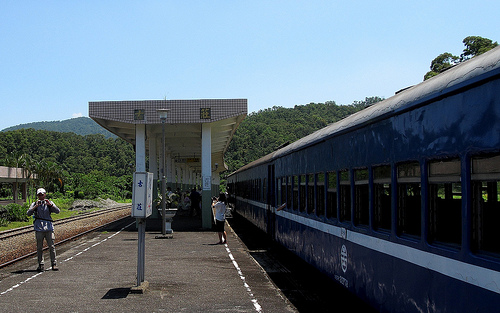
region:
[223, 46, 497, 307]
a blue train at a station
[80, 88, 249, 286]
a covering over a platform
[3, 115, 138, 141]
a mountain in the distance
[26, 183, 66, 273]
a man taking a picture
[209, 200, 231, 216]
a white shirt on a woman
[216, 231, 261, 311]
a white line on a train platform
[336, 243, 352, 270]
a white insignia on a train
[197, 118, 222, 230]
a support post at a train station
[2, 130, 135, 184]
trees in the distance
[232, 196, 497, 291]
a white stripe on a train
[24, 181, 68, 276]
a person stand on a train station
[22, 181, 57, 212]
person wearing a white cap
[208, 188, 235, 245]
woman has white shirt and black skirt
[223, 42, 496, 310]
a blue train on right side of platform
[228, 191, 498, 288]
a white stripe on side of train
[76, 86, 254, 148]
roof of train platform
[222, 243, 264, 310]
a white line on border of platform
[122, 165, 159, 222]
chinese letters on a box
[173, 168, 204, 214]
people can be seen in the platform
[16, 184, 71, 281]
man wears tane pants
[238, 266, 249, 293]
the line is white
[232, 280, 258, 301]
the line is white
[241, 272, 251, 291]
the line is white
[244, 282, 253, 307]
the line is white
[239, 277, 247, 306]
the line is white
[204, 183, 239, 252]
a woman in a white shirt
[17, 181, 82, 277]
a man standing with a camera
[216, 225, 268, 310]
a white stripe on the ground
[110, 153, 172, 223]
a white box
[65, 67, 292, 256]
a train station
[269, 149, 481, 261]
windows on the train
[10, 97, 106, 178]
mountain covered in trees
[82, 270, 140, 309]
shadow on the ground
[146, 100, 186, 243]
a light post at the train station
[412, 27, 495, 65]
the top of a green tree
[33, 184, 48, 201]
the head of a man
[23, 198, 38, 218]
the arm of a man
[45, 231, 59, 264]
the leg of a man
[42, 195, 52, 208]
the hand of a man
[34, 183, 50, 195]
a white baseball cap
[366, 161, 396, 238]
a window on the train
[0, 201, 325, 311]
a black asphalt walkway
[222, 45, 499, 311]
a train on the tracks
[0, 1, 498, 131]
a clear blue sky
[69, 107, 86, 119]
a cloud in the sky